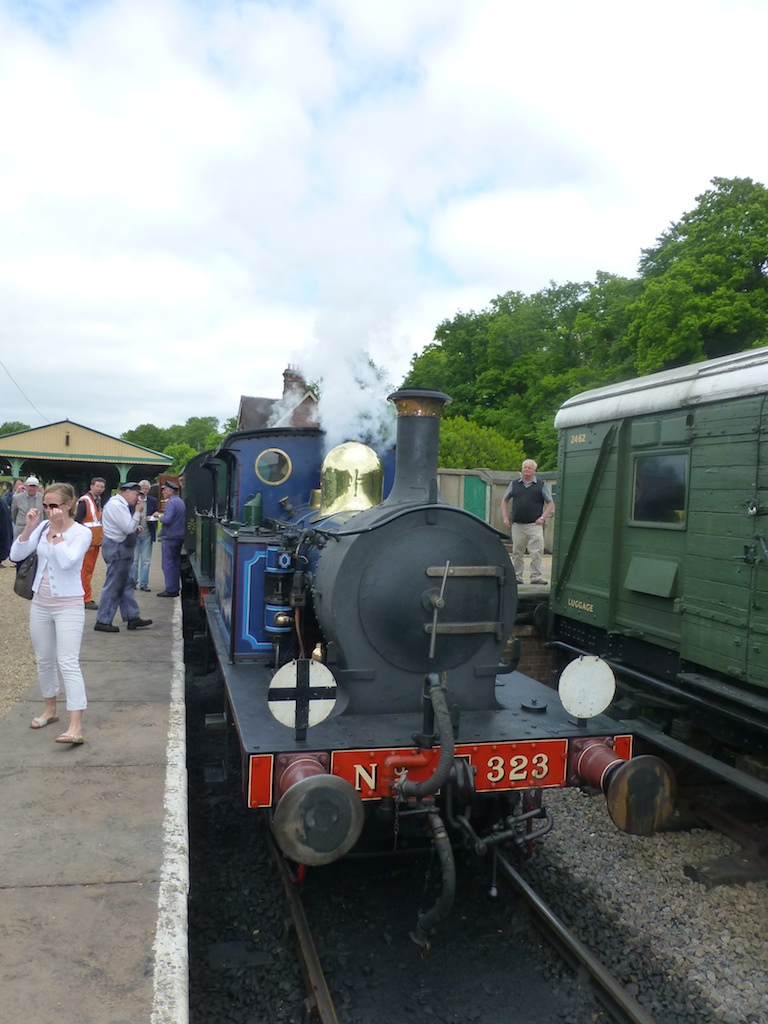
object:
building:
[0, 419, 174, 543]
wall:
[54, 427, 92, 454]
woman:
[8, 482, 93, 747]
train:
[531, 351, 768, 794]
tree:
[467, 314, 525, 371]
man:
[95, 482, 155, 633]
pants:
[30, 594, 88, 712]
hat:
[121, 480, 146, 496]